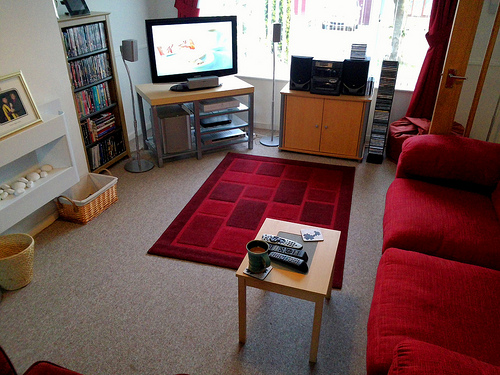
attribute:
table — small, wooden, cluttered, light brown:
[233, 202, 344, 365]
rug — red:
[142, 146, 363, 290]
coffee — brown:
[245, 238, 274, 274]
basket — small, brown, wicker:
[51, 171, 126, 223]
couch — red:
[365, 126, 499, 372]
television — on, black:
[146, 13, 241, 86]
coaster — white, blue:
[245, 268, 274, 279]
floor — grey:
[57, 224, 149, 349]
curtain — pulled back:
[407, 1, 456, 119]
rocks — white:
[10, 174, 36, 195]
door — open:
[413, 0, 490, 142]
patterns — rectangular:
[253, 159, 310, 210]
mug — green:
[238, 228, 274, 285]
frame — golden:
[12, 67, 52, 124]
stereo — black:
[283, 45, 379, 106]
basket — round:
[0, 229, 38, 293]